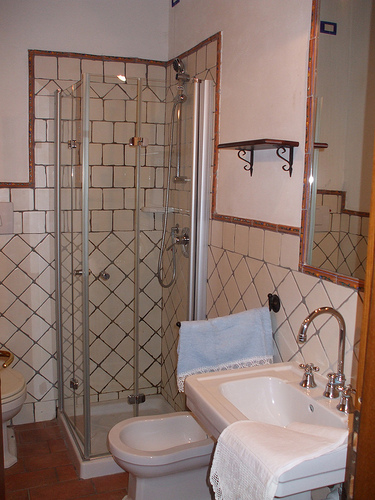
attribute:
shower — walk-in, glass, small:
[57, 58, 213, 481]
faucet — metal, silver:
[295, 306, 348, 398]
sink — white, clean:
[182, 360, 348, 497]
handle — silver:
[299, 362, 320, 389]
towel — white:
[210, 419, 350, 499]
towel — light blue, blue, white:
[176, 308, 277, 392]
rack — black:
[178, 292, 281, 329]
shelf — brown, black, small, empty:
[217, 138, 299, 175]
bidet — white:
[107, 410, 219, 500]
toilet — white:
[1, 351, 28, 469]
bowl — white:
[1, 386, 28, 420]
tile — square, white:
[248, 225, 266, 263]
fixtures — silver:
[295, 306, 357, 414]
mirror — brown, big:
[299, 1, 375, 291]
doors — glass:
[65, 81, 83, 452]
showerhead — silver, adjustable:
[171, 59, 184, 73]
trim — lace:
[208, 467, 227, 500]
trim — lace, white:
[175, 356, 276, 395]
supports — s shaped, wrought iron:
[235, 143, 295, 177]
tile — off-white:
[209, 220, 225, 249]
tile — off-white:
[220, 223, 238, 254]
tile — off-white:
[234, 223, 248, 256]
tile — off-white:
[263, 229, 282, 263]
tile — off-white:
[280, 235, 298, 271]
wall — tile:
[2, 1, 170, 425]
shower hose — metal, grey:
[158, 97, 178, 288]